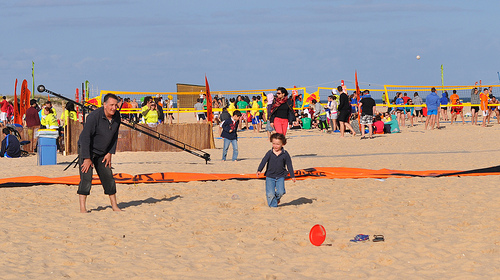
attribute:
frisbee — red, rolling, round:
[304, 222, 336, 259]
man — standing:
[58, 83, 139, 219]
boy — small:
[260, 132, 296, 208]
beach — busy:
[340, 145, 461, 163]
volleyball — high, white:
[414, 53, 424, 63]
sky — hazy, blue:
[58, 15, 434, 44]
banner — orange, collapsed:
[7, 168, 493, 184]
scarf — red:
[271, 93, 289, 106]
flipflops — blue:
[351, 229, 392, 248]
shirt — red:
[374, 120, 384, 130]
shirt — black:
[84, 103, 114, 144]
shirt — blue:
[3, 133, 21, 152]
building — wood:
[173, 77, 213, 111]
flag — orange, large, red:
[10, 81, 20, 129]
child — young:
[225, 110, 244, 166]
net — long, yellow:
[101, 90, 271, 113]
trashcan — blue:
[32, 127, 63, 168]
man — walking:
[337, 83, 354, 136]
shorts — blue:
[425, 108, 440, 117]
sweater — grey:
[81, 108, 126, 153]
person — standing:
[358, 87, 381, 139]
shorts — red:
[451, 109, 473, 115]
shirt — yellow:
[146, 111, 169, 123]